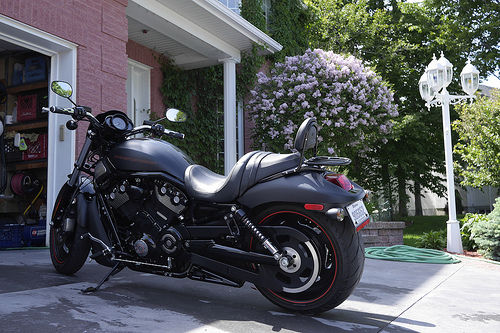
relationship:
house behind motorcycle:
[0, 0, 288, 255] [39, 80, 371, 313]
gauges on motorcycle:
[103, 112, 135, 132] [39, 80, 371, 313]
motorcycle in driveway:
[39, 80, 371, 313] [0, 242, 500, 331]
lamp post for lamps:
[435, 100, 472, 257] [415, 52, 478, 102]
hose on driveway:
[357, 235, 470, 279] [0, 242, 500, 331]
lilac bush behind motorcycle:
[248, 46, 403, 172] [18, 69, 383, 313]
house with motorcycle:
[0, 0, 404, 249] [39, 80, 371, 313]